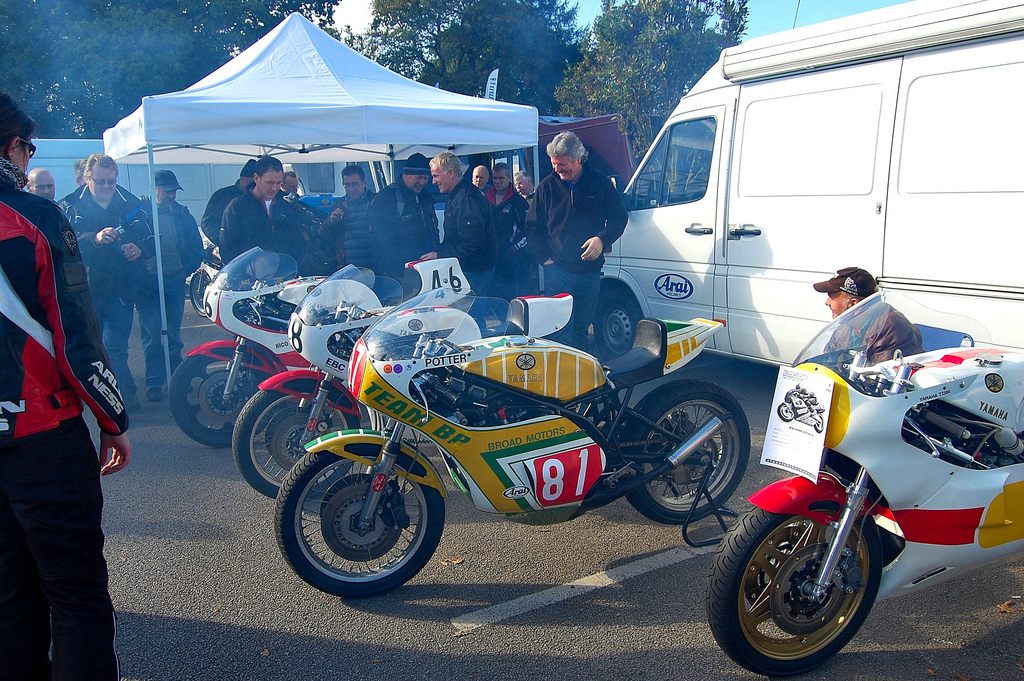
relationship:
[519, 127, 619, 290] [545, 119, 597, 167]
man with hair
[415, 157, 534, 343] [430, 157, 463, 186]
man with hair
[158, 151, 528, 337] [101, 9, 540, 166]
men standing under canopy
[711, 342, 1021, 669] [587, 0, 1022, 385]
motorcycle beside van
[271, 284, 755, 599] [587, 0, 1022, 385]
bike beside van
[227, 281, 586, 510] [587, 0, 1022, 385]
motorcycle beside van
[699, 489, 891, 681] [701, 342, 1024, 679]
front wheel on motorcycle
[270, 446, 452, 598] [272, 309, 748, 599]
front wheel on bike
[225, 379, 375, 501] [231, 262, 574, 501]
front wheel on motorcycle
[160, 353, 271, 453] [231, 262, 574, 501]
front wheel on motorcycle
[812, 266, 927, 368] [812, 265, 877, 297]
man wearing baseball cap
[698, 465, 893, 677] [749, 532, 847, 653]
wheel has rim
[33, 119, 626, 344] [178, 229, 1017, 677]
people looking at motorcycles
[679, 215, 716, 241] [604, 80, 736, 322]
handle on door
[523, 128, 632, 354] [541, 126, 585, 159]
man has hair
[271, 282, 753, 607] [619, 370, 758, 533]
bike has back wheel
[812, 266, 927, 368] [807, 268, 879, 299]
man wearing baseball cap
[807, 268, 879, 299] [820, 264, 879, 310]
baseball cap on head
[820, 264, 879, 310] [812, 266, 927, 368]
head of man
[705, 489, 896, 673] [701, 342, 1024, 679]
front wheel of motorcycle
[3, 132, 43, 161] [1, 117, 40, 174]
glasses on person's face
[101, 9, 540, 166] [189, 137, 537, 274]
canopy over people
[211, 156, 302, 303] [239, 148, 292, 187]
person has hair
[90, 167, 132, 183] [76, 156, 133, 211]
sunglasses on man's face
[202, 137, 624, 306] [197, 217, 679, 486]
men looking at bikes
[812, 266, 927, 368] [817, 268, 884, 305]
man wearing baseball cap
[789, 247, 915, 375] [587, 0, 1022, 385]
man sitting by van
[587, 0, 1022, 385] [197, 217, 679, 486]
van parked by bikes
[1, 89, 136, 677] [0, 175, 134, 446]
guy wearing jacket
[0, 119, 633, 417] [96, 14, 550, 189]
people standing under canopy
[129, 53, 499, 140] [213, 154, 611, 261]
canopy sheltering people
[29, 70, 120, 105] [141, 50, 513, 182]
trees beyond canopy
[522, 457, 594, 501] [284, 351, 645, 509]
number 81 on bike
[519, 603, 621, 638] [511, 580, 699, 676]
stripe on ground